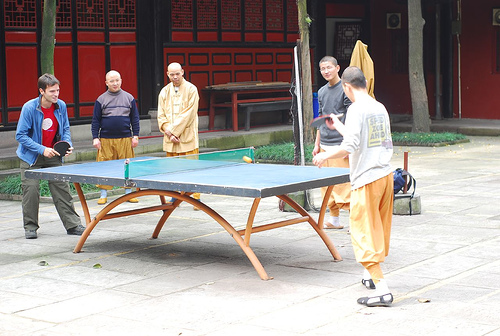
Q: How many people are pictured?
A: Five.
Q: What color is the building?
A: Red.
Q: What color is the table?
A: Green.